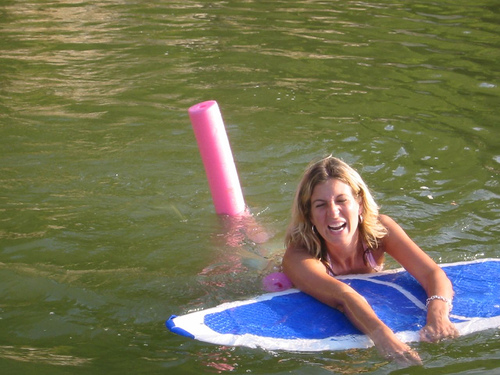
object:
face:
[308, 178, 361, 246]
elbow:
[330, 290, 351, 314]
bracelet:
[424, 295, 454, 312]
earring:
[311, 225, 316, 235]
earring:
[359, 215, 364, 224]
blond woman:
[277, 150, 461, 368]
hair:
[283, 154, 387, 257]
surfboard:
[163, 256, 500, 353]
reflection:
[195, 206, 409, 375]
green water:
[0, 0, 498, 375]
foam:
[167, 85, 278, 263]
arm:
[279, 254, 387, 341]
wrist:
[428, 305, 449, 320]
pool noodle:
[185, 99, 247, 215]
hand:
[417, 317, 461, 347]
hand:
[373, 334, 422, 366]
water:
[0, 0, 500, 375]